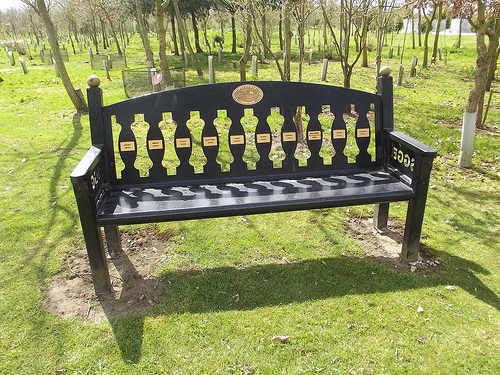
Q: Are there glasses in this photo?
A: No, there are no glasses.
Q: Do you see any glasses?
A: No, there are no glasses.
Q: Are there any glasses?
A: No, there are no glasses.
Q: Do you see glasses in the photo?
A: No, there are no glasses.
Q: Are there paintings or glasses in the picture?
A: No, there are no glasses or paintings.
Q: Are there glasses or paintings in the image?
A: No, there are no glasses or paintings.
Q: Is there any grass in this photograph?
A: Yes, there is grass.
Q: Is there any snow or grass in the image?
A: Yes, there is grass.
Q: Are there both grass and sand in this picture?
A: No, there is grass but no sand.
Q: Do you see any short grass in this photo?
A: Yes, there is short grass.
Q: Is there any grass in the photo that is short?
A: Yes, there is grass that is short.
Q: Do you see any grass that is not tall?
A: Yes, there is short grass.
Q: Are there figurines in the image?
A: No, there are no figurines.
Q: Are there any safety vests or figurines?
A: No, there are no figurines or safety vests.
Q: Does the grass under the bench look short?
A: Yes, the grass is short.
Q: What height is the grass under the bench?
A: The grass is short.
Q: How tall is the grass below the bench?
A: The grass is short.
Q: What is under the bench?
A: The grass is under the bench.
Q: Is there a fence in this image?
A: Yes, there is a fence.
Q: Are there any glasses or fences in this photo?
A: Yes, there is a fence.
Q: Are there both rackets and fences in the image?
A: No, there is a fence but no rackets.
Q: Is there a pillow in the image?
A: No, there are no pillows.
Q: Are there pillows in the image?
A: No, there are no pillows.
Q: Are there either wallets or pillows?
A: No, there are no pillows or wallets.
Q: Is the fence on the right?
A: Yes, the fence is on the right of the image.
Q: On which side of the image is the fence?
A: The fence is on the right of the image.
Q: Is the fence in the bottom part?
A: No, the fence is in the top of the image.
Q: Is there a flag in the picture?
A: No, there are no flags.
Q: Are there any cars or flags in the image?
A: No, there are no flags or cars.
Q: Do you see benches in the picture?
A: Yes, there is a bench.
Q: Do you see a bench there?
A: Yes, there is a bench.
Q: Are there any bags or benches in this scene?
A: Yes, there is a bench.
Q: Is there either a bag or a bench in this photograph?
A: Yes, there is a bench.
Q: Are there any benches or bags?
A: Yes, there is a bench.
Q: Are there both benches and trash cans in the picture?
A: No, there is a bench but no trash cans.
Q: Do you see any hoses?
A: No, there are no hoses.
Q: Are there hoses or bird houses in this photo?
A: No, there are no hoses or bird houses.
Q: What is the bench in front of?
A: The bench is in front of the plants.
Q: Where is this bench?
A: The bench is on the grass.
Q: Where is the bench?
A: The bench is on the grass.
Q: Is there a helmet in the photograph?
A: No, there are no helmets.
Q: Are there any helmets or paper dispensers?
A: No, there are no helmets or paper dispensers.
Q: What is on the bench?
A: The symbol is on the bench.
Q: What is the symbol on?
A: The symbol is on the bench.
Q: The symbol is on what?
A: The symbol is on the bench.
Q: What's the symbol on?
A: The symbol is on the bench.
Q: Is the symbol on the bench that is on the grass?
A: Yes, the symbol is on the bench.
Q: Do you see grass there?
A: Yes, there is grass.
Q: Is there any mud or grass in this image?
A: Yes, there is grass.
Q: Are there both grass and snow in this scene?
A: No, there is grass but no snow.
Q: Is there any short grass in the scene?
A: Yes, there is short grass.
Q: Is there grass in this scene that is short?
A: Yes, there is grass that is short.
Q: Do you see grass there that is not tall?
A: Yes, there is short grass.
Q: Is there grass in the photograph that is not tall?
A: Yes, there is short grass.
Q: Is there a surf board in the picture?
A: No, there are no surfboards.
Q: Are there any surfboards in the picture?
A: No, there are no surfboards.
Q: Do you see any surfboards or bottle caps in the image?
A: No, there are no surfboards or bottle caps.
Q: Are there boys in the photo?
A: No, there are no boys.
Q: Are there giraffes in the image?
A: No, there are no giraffes.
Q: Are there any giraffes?
A: No, there are no giraffes.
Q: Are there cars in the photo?
A: No, there are no cars.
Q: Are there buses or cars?
A: No, there are no cars or buses.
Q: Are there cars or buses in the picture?
A: No, there are no cars or buses.